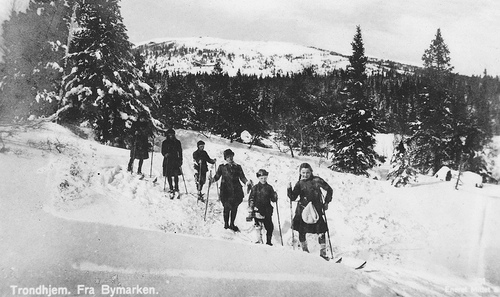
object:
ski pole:
[316, 200, 336, 260]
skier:
[243, 168, 282, 247]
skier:
[207, 147, 254, 233]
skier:
[190, 141, 215, 204]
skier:
[157, 124, 188, 201]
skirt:
[289, 198, 329, 234]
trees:
[410, 24, 483, 166]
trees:
[327, 23, 382, 176]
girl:
[286, 163, 336, 262]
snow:
[133, 36, 421, 80]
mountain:
[122, 37, 500, 131]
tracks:
[60, 253, 329, 281]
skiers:
[118, 108, 156, 181]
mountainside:
[309, 51, 500, 129]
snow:
[0, 113, 500, 296]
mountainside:
[0, 0, 498, 294]